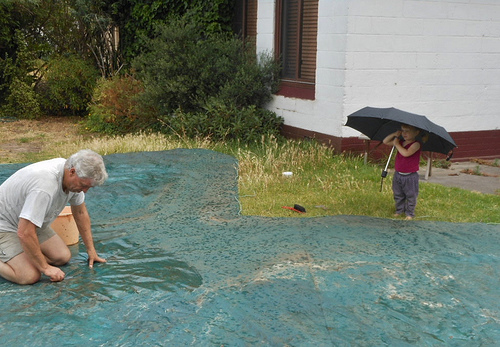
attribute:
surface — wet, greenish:
[0, 236, 202, 345]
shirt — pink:
[391, 139, 422, 172]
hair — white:
[66, 150, 108, 185]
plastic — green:
[2, 147, 497, 346]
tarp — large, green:
[2, 135, 497, 345]